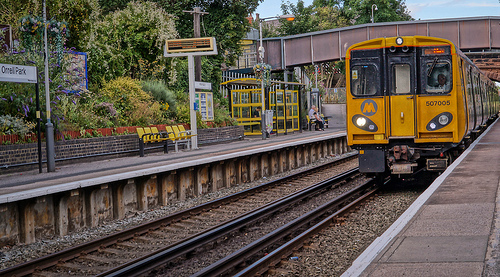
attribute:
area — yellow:
[221, 61, 307, 134]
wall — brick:
[16, 134, 155, 165]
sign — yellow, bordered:
[155, 30, 239, 58]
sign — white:
[190, 71, 224, 132]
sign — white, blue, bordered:
[46, 44, 114, 119]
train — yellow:
[324, 40, 492, 222]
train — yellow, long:
[332, 36, 484, 193]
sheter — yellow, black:
[211, 54, 328, 138]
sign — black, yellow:
[139, 20, 243, 55]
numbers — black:
[418, 95, 465, 125]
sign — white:
[6, 60, 73, 92]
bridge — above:
[296, 10, 498, 40]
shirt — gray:
[301, 90, 321, 110]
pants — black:
[307, 117, 323, 130]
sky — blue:
[389, 0, 495, 25]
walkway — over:
[256, 11, 473, 71]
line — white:
[343, 185, 416, 273]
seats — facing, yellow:
[122, 130, 205, 151]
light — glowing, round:
[355, 116, 367, 126]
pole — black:
[33, 80, 43, 172]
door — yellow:
[387, 55, 417, 136]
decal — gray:
[360, 99, 378, 119]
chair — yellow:
[136, 126, 153, 156]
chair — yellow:
[142, 126, 161, 141]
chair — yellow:
[149, 125, 171, 153]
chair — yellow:
[163, 123, 185, 152]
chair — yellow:
[170, 124, 191, 139]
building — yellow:
[220, 76, 308, 135]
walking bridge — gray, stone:
[255, 13, 485, 74]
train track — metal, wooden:
[2, 149, 362, 275]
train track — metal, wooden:
[190, 173, 394, 274]